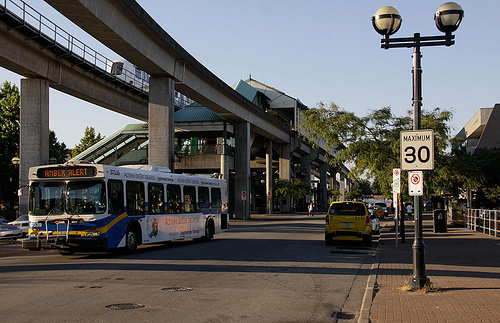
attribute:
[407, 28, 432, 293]
post — iron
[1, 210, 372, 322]
road — paved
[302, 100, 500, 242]
tree — green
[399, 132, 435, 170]
sign — white, speed limit, black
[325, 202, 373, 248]
cab — yellow, parked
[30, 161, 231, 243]
bus — yellow, blue, white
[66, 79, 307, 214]
building — silver, tall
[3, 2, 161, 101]
fence — metal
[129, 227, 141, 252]
wheel — black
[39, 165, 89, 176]
letters — yellow, orange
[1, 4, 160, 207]
bridge — large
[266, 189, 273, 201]
sign — red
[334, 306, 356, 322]
drain — metal